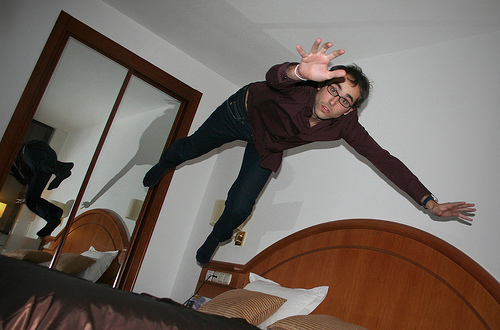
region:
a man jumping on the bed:
[98, 10, 498, 329]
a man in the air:
[77, 30, 422, 324]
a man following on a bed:
[95, 23, 464, 329]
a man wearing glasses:
[107, 46, 497, 250]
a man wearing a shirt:
[150, 40, 457, 329]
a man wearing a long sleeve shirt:
[90, 21, 455, 278]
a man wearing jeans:
[125, 17, 432, 289]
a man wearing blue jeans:
[122, 20, 467, 303]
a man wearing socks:
[117, 37, 470, 327]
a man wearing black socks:
[91, 20, 446, 323]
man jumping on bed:
[146, 34, 480, 269]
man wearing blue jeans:
[141, 40, 476, 267]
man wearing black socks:
[132, 39, 474, 268]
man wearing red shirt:
[140, 31, 475, 273]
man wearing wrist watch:
[421, 190, 438, 212]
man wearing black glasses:
[309, 67, 363, 117]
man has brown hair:
[315, 64, 372, 123]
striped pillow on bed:
[200, 287, 280, 328]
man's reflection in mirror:
[8, 140, 65, 240]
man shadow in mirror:
[80, 105, 176, 210]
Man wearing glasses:
[311, 63, 366, 153]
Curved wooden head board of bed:
[239, 216, 485, 313]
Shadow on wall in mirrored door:
[86, 74, 160, 241]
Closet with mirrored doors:
[6, 34, 165, 296]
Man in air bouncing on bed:
[113, 31, 485, 259]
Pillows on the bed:
[190, 273, 290, 327]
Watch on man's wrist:
[389, 171, 450, 225]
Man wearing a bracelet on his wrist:
[280, 60, 322, 90]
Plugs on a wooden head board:
[193, 263, 237, 291]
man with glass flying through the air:
[141, 37, 421, 262]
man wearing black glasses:
[320, 58, 378, 137]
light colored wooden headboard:
[184, 197, 489, 328]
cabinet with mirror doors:
[25, 24, 146, 289]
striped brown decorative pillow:
[195, 280, 276, 324]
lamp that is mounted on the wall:
[198, 180, 250, 247]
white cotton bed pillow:
[250, 265, 339, 327]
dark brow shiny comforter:
[10, 248, 171, 328]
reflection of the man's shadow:
[136, 77, 194, 191]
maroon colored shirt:
[257, 75, 411, 195]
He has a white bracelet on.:
[284, 61, 313, 91]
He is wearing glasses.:
[322, 71, 360, 109]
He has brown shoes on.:
[246, 61, 431, 208]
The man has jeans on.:
[142, 98, 289, 258]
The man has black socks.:
[140, 157, 239, 300]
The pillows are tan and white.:
[211, 278, 318, 328]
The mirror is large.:
[14, 13, 178, 308]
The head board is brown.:
[213, 213, 485, 328]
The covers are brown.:
[5, 246, 251, 327]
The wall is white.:
[402, 105, 479, 177]